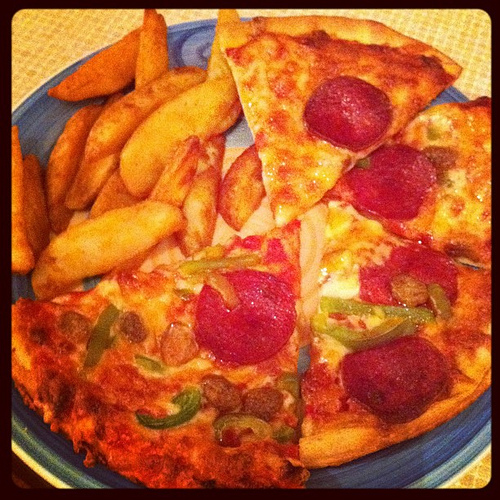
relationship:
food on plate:
[21, 62, 479, 422] [11, 15, 490, 488]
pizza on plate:
[206, 21, 479, 439] [11, 15, 490, 488]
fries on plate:
[10, 38, 252, 237] [11, 15, 490, 488]